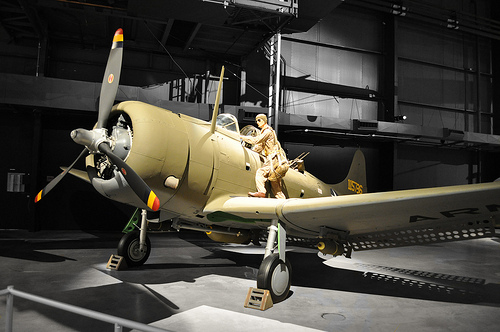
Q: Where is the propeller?
A: On front of the plane.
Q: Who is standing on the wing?
A: Pilot.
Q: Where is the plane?
A: In a hangar.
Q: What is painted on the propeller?
A: Red and yellow stripes.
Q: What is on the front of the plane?
A: A propeller.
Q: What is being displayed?
A: Airplane.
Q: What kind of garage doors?
A: Two story.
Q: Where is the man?
A: Boarding the plane.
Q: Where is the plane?
A: Hangar.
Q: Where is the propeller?
A: On the front of the plane.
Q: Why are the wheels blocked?
A: So the plane can't move.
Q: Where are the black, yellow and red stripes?
A: On the propeller.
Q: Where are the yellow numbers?
A: On the tail of the plane.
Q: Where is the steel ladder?
A: Behind the plane.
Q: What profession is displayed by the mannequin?
A: Military pilot.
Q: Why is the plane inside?
A: Exhibit.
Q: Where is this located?
A: Inside a hanger.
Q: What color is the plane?
A: Brown.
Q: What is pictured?
A: A plane.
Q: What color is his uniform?
A: Beige and brown.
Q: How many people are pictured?
A: One.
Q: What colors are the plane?
A: Red, yellow, and green.